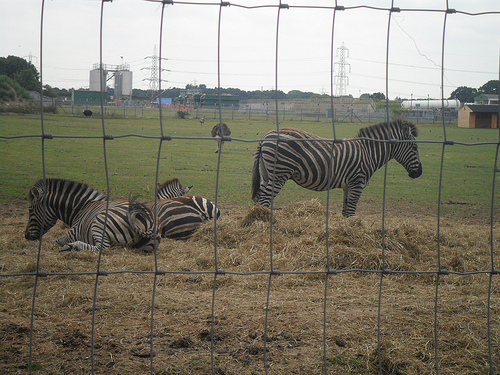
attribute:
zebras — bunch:
[18, 126, 430, 265]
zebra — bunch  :
[137, 162, 233, 253]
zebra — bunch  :
[250, 118, 423, 216]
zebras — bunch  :
[16, 127, 495, 278]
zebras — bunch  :
[50, 164, 368, 224]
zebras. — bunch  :
[21, 98, 439, 268]